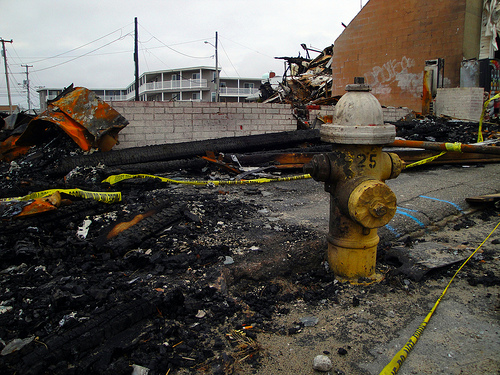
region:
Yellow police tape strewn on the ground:
[145, 166, 304, 193]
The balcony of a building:
[146, 51, 223, 100]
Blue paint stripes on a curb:
[340, 176, 476, 247]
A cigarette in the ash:
[232, 310, 261, 336]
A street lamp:
[196, 32, 222, 75]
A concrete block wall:
[133, 98, 302, 158]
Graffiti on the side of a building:
[350, 43, 435, 114]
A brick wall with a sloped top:
[329, 1, 386, 124]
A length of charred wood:
[104, 177, 212, 267]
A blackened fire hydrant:
[302, 74, 418, 295]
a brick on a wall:
[114, 100, 135, 107]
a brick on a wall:
[133, 99, 153, 106]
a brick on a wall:
[156, 98, 178, 109]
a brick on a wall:
[123, 104, 149, 116]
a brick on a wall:
[136, 110, 151, 120]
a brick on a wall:
[186, 106, 205, 116]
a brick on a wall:
[146, 130, 171, 142]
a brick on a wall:
[126, 132, 146, 140]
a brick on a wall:
[126, 115, 148, 127]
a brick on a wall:
[244, 114, 261, 119]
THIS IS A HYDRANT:
[311, 73, 428, 288]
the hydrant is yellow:
[303, 148, 405, 280]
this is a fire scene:
[3, 87, 230, 372]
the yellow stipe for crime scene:
[379, 222, 486, 374]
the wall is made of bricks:
[24, 107, 311, 132]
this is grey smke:
[354, 55, 459, 117]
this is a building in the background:
[37, 62, 299, 107]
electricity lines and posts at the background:
[1, 0, 265, 107]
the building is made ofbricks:
[318, 0, 474, 121]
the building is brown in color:
[329, 0, 484, 104]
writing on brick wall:
[372, 55, 415, 82]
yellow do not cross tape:
[375, 303, 422, 370]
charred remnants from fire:
[54, 322, 150, 352]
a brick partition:
[150, 107, 245, 140]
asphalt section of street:
[426, 170, 479, 198]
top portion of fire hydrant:
[313, 75, 390, 150]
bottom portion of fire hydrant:
[307, 145, 404, 280]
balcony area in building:
[143, 75, 208, 95]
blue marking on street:
[415, 182, 457, 219]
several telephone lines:
[35, 46, 122, 63]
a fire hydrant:
[309, 77, 405, 289]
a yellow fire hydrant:
[314, 65, 410, 283]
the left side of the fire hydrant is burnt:
[308, 66, 402, 284]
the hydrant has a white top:
[304, 72, 409, 269]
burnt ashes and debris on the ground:
[16, 82, 331, 364]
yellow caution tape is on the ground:
[32, 154, 494, 374]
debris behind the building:
[253, 30, 357, 127]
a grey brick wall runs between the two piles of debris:
[30, 95, 427, 135]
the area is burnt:
[15, 89, 324, 368]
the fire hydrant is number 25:
[304, 76, 415, 291]